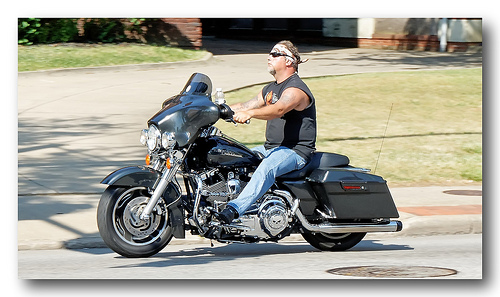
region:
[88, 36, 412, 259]
Man riding a motorcycle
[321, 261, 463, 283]
Manhole cover in the street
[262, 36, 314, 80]
Man wearing a bandana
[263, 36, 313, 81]
Man wearing black sunglasses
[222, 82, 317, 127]
Tattoos on arms of motorcycle rider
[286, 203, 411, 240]
Chrome motorcycle tail pipe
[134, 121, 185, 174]
Lights on front of motorcycle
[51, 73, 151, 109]
Concrete driveway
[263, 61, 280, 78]
Man with a goatee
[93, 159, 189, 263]
Front tire assembly of a motorcycle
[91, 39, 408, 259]
Man riding a motorcycle.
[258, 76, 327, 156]
Man wearing short sleeve black shirt.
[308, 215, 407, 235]
Chrome exhaust pipe on motorcycle.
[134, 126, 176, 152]
Headlights on a motorcycle.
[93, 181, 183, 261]
Front tire of motorcycle.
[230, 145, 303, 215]
Man wearing blue jeans.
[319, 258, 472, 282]
Man hole cover in street.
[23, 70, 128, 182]
Drive way leading to house.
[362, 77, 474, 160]
Brown grass on lawn.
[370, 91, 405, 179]
Antenna on back of motorcycle.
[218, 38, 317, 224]
Man wearing a white bandana.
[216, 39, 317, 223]
Man wearing black sunglasses.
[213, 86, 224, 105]
A bottle of water.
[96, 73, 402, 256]
A large black motorcycle.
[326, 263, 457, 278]
Rusty manhole cover.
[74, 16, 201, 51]
A brick wall in the background.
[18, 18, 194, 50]
A couple of bushes.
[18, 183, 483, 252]
A long side walk.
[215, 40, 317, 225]
Man wearing a pair of blue jeans.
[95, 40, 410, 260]
The man is riding a black and chrome motorcycle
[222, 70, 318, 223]
The man is wearing blue jeans and a black sleeveless shirt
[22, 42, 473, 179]
The grass is green and brown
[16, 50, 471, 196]
The concrete driveway is gray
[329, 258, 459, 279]
The manhole cover is brown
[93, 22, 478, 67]
The house is made of red brick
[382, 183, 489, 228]
The sidewalk is grey and red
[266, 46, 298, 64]
The man is wearing glasses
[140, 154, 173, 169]
The motorcycle has 2 orange lights on the front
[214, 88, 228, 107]
There is a clear water bottle in the cup holder of the motorcycle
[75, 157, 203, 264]
This is a tire.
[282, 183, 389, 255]
This is the back tire.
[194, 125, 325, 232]
These are jeans.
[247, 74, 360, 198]
This is a tanktop.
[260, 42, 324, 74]
This is a man in a bandana.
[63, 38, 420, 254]
This is a man on a motorcycle.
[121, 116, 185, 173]
These are headlights.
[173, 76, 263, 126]
These are handlebars.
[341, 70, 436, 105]
This is grass.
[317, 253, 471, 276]
This is a man hole.